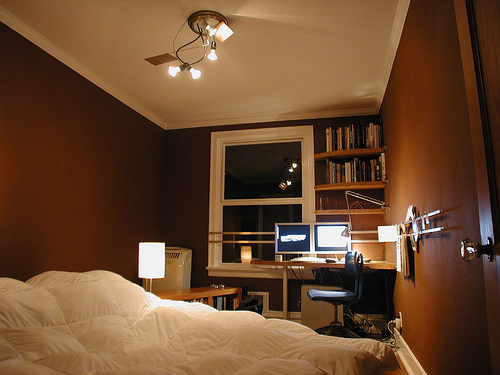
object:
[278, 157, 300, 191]
light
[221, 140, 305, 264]
glass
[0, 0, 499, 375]
bedroom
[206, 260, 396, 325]
desk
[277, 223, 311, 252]
monitor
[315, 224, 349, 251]
monitor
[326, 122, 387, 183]
books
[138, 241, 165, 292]
lamp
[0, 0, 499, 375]
wall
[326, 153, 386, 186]
books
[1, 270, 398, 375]
comforter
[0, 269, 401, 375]
bed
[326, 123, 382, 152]
books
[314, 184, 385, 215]
shelf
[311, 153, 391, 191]
shelf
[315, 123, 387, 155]
shelf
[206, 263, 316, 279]
sill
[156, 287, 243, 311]
table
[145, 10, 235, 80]
lights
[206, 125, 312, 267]
window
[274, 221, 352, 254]
computers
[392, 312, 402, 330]
electrical socket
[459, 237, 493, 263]
door knob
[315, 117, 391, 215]
book shelf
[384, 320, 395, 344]
wire cord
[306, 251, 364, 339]
chair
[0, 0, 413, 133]
ceiling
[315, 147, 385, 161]
bookshelf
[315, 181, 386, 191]
bookshelf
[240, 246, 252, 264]
candle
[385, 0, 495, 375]
door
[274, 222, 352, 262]
desktop computers